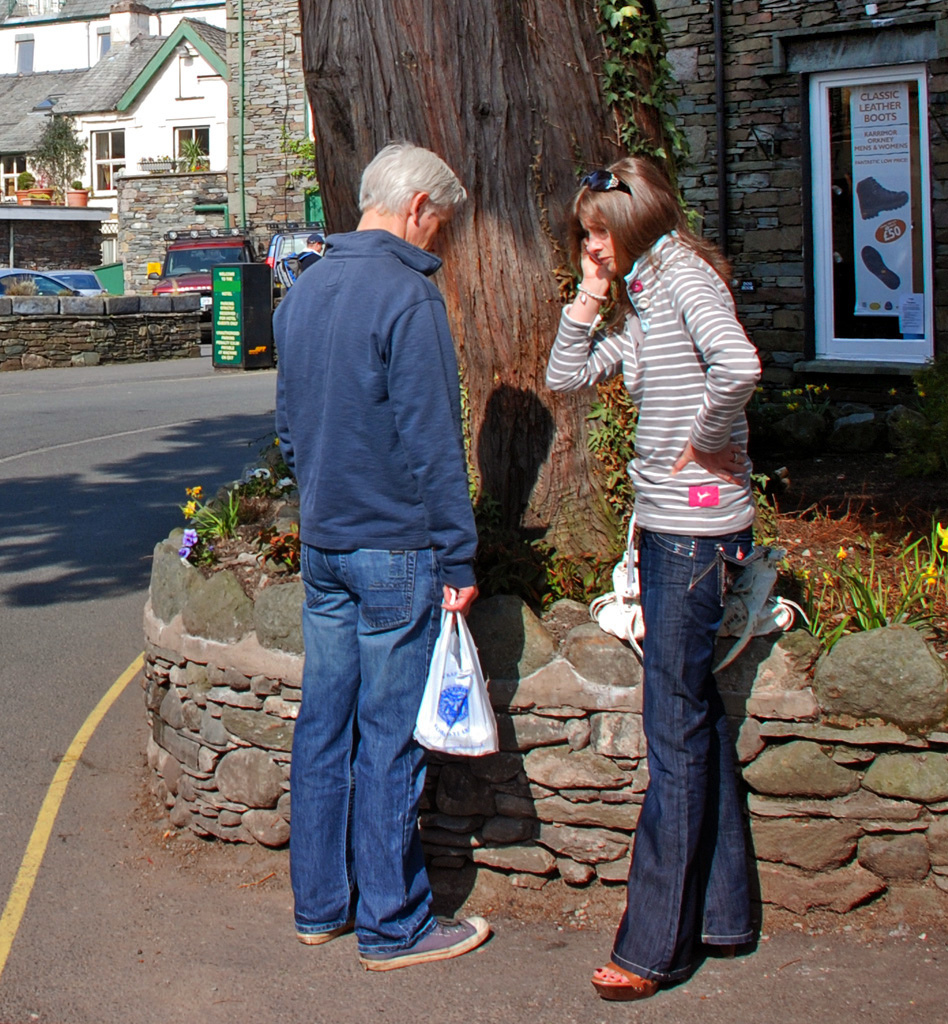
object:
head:
[579, 159, 673, 273]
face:
[579, 202, 618, 273]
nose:
[586, 241, 603, 257]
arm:
[545, 293, 623, 391]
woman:
[544, 158, 761, 1002]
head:
[359, 145, 454, 252]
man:
[271, 143, 489, 968]